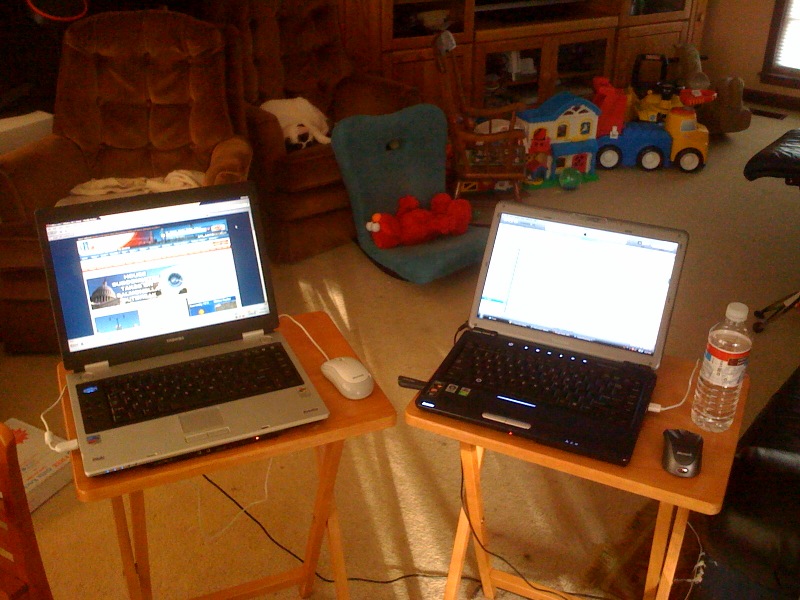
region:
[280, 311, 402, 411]
a white computer mouse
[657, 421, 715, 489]
a black wireless computer mouse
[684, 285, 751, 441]
a bottle of drinking water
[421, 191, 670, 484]
a laptop computer on a table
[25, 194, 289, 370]
the screen monitor of a laptop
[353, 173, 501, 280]
a stuffed cartoon character toy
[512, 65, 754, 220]
children's toys on the floor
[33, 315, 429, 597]
foldable wooden table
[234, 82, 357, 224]
a pet cat on the couch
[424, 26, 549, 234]
a small wooden chair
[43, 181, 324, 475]
the laptop is silver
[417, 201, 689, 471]
the laptop is on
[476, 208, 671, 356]
the monitor is bright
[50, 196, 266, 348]
browser opened on screen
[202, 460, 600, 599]
the cords are black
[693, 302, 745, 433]
a bottle of water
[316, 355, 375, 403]
the mouse is white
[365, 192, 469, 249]
a stuffed elmo toy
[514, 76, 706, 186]
a group of toys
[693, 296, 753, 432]
bottle of water next to black mouse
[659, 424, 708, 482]
black and gray wireless mouse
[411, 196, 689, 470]
black and gray laptop next to waterbottle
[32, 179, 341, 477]
black and silver laptop next to white mouse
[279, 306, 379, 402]
white and gray mouse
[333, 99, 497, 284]
stuffed elmo doll on green chair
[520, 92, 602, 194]
blue and white toy house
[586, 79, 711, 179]
blue, yellow and red toy truck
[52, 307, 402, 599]
wooden table with silver and black laptop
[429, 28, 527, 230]
small wooden rocking chair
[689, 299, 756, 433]
a water bottle next to the laptop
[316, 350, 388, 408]
a white and gray computer mouse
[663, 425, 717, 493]
a black and gray computer mouse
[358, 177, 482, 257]
a red elmo in a seat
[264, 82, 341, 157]
a white cat in a chair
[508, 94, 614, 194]
a toy house with a blue roof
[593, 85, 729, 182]
a toy truck that is blue and yellow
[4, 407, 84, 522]
a white box on the floor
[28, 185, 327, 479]
a laptop with a sliver and black base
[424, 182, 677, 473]
laptop on the table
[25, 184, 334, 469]
laptop on the table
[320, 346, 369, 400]
mouse on the table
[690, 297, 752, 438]
water bottle on the table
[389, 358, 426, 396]
flash drive in the laptop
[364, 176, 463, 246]
teddy bear on the chair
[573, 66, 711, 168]
toy car is yellow and blue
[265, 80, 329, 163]
cat sleeping on the chair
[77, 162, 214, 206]
white cloth on the chair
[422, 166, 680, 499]
a small laptop computer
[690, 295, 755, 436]
A bottle of bottled water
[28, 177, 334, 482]
An opened laptop computer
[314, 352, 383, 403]
A white computer mouse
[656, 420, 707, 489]
A black computer mouse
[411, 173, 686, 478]
An opened laptop computer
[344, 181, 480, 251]
A plush Elmo doll on a pillow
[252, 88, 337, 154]
A cat sleeping on a chair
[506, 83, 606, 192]
A children's plastic toy house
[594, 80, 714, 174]
A little tykes toy truck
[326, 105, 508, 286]
A blue rocking chair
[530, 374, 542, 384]
A key on a keyboard.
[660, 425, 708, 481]
Wireless computer mouse on a wooden desk